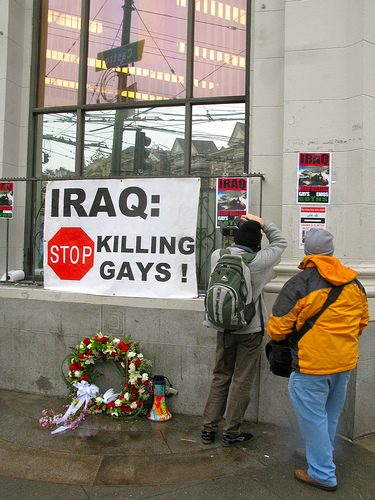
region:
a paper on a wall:
[297, 155, 335, 188]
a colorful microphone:
[148, 367, 180, 426]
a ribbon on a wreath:
[71, 375, 97, 407]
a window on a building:
[36, 133, 92, 173]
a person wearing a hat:
[300, 225, 338, 259]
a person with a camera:
[217, 208, 259, 233]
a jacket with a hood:
[298, 251, 364, 286]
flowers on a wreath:
[97, 386, 137, 422]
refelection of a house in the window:
[219, 135, 247, 171]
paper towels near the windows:
[5, 261, 29, 291]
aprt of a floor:
[167, 465, 184, 491]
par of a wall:
[162, 378, 173, 407]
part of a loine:
[168, 429, 193, 458]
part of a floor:
[167, 465, 184, 489]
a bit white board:
[35, 142, 210, 300]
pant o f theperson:
[278, 369, 370, 469]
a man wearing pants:
[261, 398, 373, 472]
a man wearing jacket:
[269, 286, 372, 365]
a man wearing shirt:
[194, 223, 309, 344]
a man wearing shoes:
[287, 450, 332, 483]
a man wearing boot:
[193, 415, 263, 460]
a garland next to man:
[8, 318, 161, 432]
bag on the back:
[193, 235, 287, 356]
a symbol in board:
[31, 232, 89, 277]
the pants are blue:
[281, 372, 360, 482]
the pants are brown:
[206, 336, 266, 423]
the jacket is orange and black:
[286, 265, 371, 379]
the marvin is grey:
[302, 226, 337, 255]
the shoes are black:
[204, 416, 258, 453]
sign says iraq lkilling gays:
[44, 178, 198, 302]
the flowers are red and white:
[56, 332, 148, 420]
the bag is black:
[253, 329, 306, 374]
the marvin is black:
[226, 212, 269, 253]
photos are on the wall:
[294, 163, 328, 200]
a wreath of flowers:
[36, 330, 152, 432]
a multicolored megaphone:
[147, 369, 180, 423]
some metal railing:
[1, 172, 267, 307]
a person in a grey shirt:
[196, 212, 289, 445]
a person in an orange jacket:
[263, 225, 371, 490]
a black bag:
[263, 279, 350, 379]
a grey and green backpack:
[199, 248, 257, 328]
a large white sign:
[42, 177, 201, 300]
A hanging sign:
[215, 174, 249, 229]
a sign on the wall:
[295, 149, 330, 203]